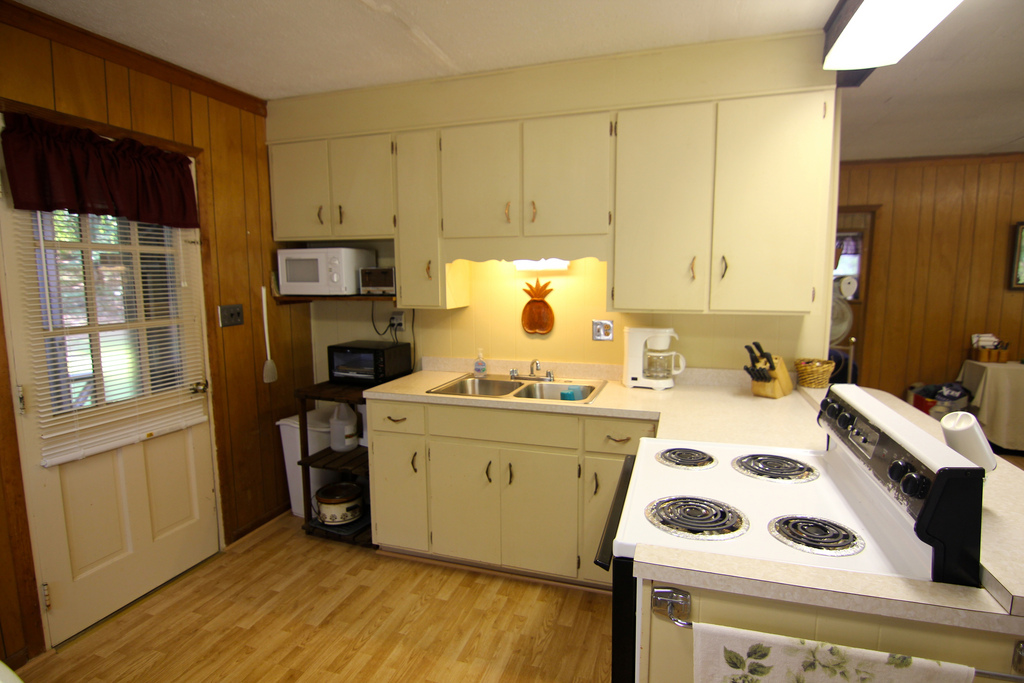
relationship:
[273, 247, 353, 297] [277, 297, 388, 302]
microwave on a shelf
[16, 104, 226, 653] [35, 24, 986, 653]
door in kitchen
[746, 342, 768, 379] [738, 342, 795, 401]
knives in block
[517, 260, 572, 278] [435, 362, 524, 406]
light above sink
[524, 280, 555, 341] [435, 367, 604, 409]
ceramic above sink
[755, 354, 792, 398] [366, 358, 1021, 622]
block on counter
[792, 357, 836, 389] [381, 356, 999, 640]
basket on counter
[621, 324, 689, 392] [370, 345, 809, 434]
coffee pot on counter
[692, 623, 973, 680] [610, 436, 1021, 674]
towel by oven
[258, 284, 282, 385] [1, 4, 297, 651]
flyswatter on wall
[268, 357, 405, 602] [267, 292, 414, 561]
crockpot on shelf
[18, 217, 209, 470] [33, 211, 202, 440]
blinds on window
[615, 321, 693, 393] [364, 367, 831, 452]
coffee pot on counter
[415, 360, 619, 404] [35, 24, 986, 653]
sink in kitchen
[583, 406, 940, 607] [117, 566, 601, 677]
stove above ground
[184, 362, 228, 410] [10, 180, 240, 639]
knob on door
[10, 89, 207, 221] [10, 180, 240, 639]
valance on door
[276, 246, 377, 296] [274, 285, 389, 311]
microwave on shelf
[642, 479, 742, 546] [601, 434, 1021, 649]
burner on stovetop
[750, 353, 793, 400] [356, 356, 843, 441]
block on counter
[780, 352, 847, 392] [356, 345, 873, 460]
basket on counter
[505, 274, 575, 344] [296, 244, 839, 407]
pineapple on wall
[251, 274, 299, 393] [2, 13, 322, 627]
flyswatter on wall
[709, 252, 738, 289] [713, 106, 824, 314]
handle of kitchen cabinet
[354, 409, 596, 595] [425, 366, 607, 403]
cabinets under sink